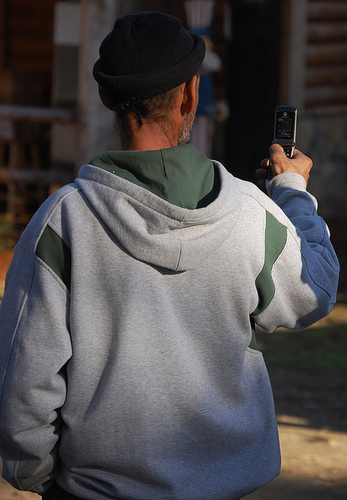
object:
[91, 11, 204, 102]
hat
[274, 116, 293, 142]
screen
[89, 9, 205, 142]
head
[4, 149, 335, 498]
shirt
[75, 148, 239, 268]
hooded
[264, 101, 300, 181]
cell phone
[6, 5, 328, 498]
man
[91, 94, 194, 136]
hair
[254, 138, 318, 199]
hand